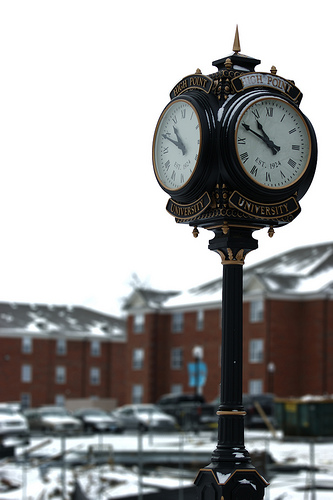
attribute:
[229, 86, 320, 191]
clock — white, black, fancy, gold, tall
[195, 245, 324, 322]
roof — brown, covered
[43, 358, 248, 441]
car — parking, colored, grey, bunch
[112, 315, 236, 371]
building — brick, red, brown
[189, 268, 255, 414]
metal — black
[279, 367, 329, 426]
dumpster — green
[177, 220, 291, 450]
pole — blue, black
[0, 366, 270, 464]
cars — parked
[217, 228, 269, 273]
leaf — golden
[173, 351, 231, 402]
banner — blue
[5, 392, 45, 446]
truck — pickup, grey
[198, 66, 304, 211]
point — high